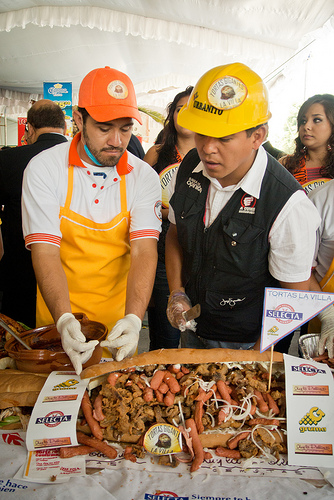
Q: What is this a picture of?
A: A sandwich.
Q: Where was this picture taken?
A: Daytime.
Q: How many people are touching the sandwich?
A: One.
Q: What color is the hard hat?
A: Yellow.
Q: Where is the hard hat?
A: On the man's head.